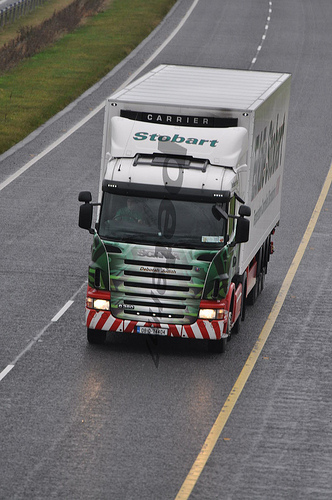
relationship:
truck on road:
[78, 64, 284, 349] [1, 0, 330, 499]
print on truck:
[132, 131, 218, 148] [78, 64, 284, 349]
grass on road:
[3, 36, 89, 109] [186, 4, 320, 498]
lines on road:
[1, 1, 272, 384] [75, 5, 331, 192]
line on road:
[170, 165, 330, 498] [1, 0, 330, 499]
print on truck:
[132, 127, 218, 148] [78, 64, 284, 349]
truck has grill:
[78, 64, 292, 358] [100, 242, 217, 325]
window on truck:
[94, 193, 238, 250] [69, 60, 305, 365]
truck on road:
[78, 64, 292, 358] [101, 3, 331, 217]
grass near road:
[8, 64, 55, 108] [1, 0, 330, 499]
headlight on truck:
[198, 306, 217, 320] [78, 64, 284, 349]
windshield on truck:
[97, 190, 227, 246] [78, 64, 284, 349]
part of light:
[197, 306, 208, 320] [196, 305, 218, 320]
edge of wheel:
[218, 337, 230, 353] [213, 297, 231, 352]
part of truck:
[205, 163, 224, 180] [78, 64, 284, 349]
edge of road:
[222, 383, 275, 427] [1, 0, 330, 499]